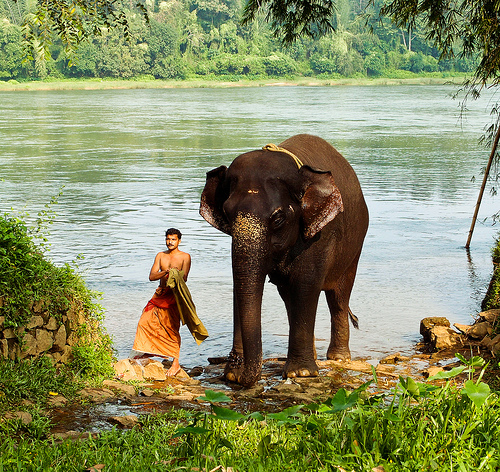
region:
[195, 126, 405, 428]
an elephant standing outside water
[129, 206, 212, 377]
a man coming out of the water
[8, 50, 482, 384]
a still body of water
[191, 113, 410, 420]
and elephant standing outside the water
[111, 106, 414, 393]
a man standing next to an elephant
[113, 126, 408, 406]
a man and an elephant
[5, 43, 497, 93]
a row of bushes by the water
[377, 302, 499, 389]
rocks next to the water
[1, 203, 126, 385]
plants growing on a rock wall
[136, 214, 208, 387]
a man holding a towel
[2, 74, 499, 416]
a man an elephant on the water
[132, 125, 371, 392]
a man and his elephant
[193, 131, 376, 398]
a wet elephant coming out of water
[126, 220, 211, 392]
a dark haired man is skirt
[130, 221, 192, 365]
a skirt on the man by water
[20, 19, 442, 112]
green forest beyond water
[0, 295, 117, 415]
rocks and grass by water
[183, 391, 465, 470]
lush green grass by waters edge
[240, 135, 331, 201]
the elephant has a rope around neck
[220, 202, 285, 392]
the elephants large trunk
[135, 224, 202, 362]
the man is standing on the rocks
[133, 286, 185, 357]
the man is wearing a cloth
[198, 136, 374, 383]
the elephant is brown in color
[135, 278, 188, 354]
the cloth is orange in color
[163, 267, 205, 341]
the man is holding cloth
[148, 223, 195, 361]
the man is facing the viewer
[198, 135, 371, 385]
the elephant is standing still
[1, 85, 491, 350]
a river is in the middle ground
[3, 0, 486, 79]
a forrest is in the background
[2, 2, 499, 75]
the forrest is green in color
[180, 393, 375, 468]
Grass at the edge of the water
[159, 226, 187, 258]
Man with a mustache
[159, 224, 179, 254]
Man with black hair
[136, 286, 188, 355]
Man wearing an orange skirt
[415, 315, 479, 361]
Rocks at the edge of the water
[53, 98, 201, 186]
Body of water in movement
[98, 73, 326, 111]
Water shore line at a distance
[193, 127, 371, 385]
Big brown elephant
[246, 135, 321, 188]
Rope around an elephants neck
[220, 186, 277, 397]
An elephants long trunk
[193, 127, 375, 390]
Elephant standing near water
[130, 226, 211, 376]
Person standing near water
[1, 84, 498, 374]
Large volume of water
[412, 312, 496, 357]
Stones by the water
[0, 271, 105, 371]
Pile of stones by the water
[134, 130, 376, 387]
Man standing next to an elephant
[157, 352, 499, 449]
Plants with wide leaves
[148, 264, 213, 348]
Hands holding a cloth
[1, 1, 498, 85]
Thick bushes in the background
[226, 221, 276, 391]
Long snout of an elephant